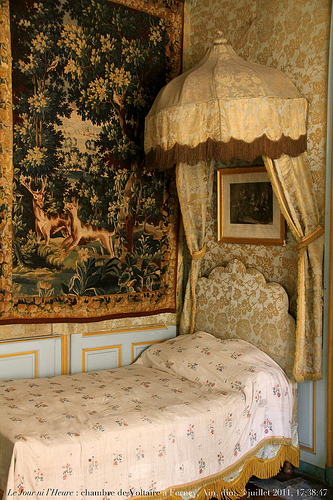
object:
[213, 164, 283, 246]
photo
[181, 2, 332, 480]
wall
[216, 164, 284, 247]
frame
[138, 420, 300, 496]
bed skirt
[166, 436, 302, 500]
fringe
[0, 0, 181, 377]
wall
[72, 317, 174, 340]
edge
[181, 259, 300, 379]
headboard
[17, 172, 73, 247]
buck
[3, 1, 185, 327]
tapestry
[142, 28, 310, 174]
feature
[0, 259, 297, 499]
bed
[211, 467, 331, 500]
floor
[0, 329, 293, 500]
bed spread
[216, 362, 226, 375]
flower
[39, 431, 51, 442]
flower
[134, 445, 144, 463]
flower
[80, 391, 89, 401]
flower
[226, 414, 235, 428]
flower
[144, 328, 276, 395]
pillow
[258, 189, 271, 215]
people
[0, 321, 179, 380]
wainscoating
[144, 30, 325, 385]
canopy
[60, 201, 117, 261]
deer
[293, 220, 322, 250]
tie back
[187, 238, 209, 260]
tie back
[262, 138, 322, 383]
curtain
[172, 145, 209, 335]
curtain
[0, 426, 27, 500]
foot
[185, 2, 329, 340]
wallpaper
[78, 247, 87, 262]
flower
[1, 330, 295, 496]
bed cover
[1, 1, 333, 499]
bedroom